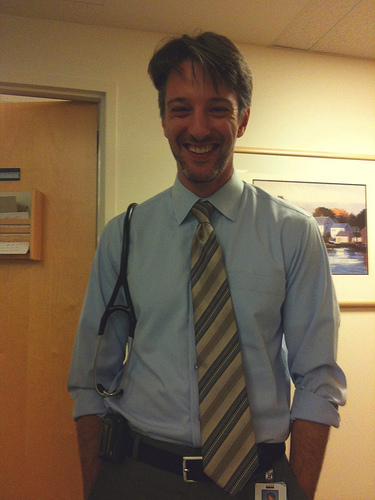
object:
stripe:
[208, 419, 255, 486]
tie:
[189, 203, 261, 499]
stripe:
[184, 221, 204, 257]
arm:
[277, 210, 346, 499]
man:
[66, 28, 348, 500]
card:
[255, 481, 286, 499]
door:
[0, 100, 99, 499]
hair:
[146, 28, 253, 120]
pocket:
[275, 452, 306, 499]